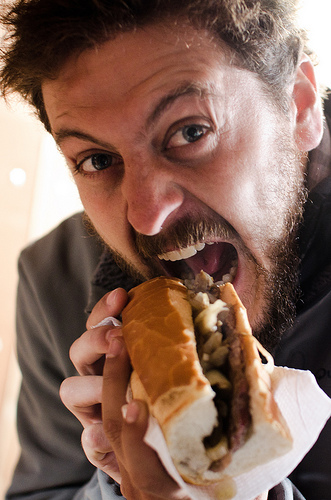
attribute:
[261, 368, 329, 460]
paper — white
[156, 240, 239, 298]
mouth — opened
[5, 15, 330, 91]
hair — brown, thick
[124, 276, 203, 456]
bread roll — cracked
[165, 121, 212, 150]
eye — blue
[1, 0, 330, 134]
hair — brown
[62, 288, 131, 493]
hand — tanner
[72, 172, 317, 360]
beard — brown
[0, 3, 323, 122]
hair — dark